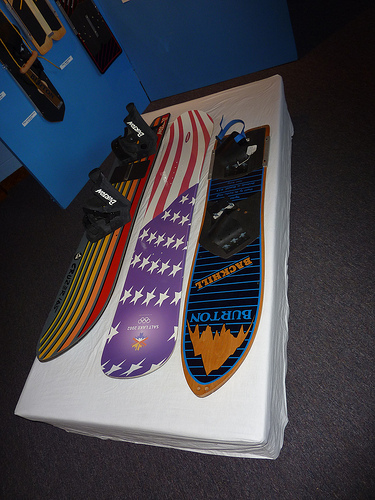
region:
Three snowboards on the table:
[75, 99, 250, 397]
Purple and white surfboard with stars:
[108, 259, 179, 370]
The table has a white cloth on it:
[94, 390, 252, 476]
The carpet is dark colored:
[290, 327, 347, 439]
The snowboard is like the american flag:
[119, 100, 205, 327]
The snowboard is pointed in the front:
[178, 328, 236, 428]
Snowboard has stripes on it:
[73, 237, 101, 326]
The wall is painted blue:
[108, 28, 246, 92]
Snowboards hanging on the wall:
[0, 13, 85, 107]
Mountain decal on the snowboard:
[185, 315, 245, 382]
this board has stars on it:
[129, 283, 148, 311]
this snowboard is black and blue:
[217, 289, 251, 319]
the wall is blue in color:
[150, 20, 193, 50]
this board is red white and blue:
[151, 156, 178, 275]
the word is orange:
[196, 255, 245, 320]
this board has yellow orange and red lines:
[49, 320, 80, 343]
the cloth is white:
[218, 95, 259, 110]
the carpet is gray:
[35, 455, 90, 477]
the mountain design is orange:
[189, 319, 237, 367]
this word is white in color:
[86, 181, 123, 213]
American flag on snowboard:
[97, 106, 212, 375]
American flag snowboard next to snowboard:
[92, 104, 212, 378]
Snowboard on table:
[181, 120, 268, 394]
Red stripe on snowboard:
[150, 107, 184, 217]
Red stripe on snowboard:
[191, 106, 208, 152]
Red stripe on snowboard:
[137, 112, 172, 212]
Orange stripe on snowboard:
[52, 150, 144, 352]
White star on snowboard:
[151, 283, 169, 307]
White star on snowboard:
[117, 356, 144, 376]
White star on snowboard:
[115, 283, 134, 305]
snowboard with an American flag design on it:
[102, 107, 187, 393]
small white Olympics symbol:
[134, 316, 156, 324]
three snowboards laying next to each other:
[28, 111, 297, 417]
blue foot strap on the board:
[206, 117, 272, 148]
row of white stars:
[121, 282, 183, 312]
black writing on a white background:
[14, 110, 44, 129]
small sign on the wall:
[56, 51, 80, 71]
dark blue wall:
[95, 2, 302, 90]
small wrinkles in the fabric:
[77, 335, 109, 378]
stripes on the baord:
[24, 243, 124, 363]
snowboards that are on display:
[19, 78, 309, 422]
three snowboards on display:
[36, 90, 279, 401]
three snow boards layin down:
[42, 58, 352, 429]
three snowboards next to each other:
[65, 86, 293, 392]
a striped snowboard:
[37, 115, 167, 358]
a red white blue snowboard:
[115, 111, 201, 381]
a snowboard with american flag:
[100, 91, 187, 380]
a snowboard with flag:
[100, 93, 192, 389]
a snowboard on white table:
[58, 86, 304, 396]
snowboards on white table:
[32, 69, 302, 393]